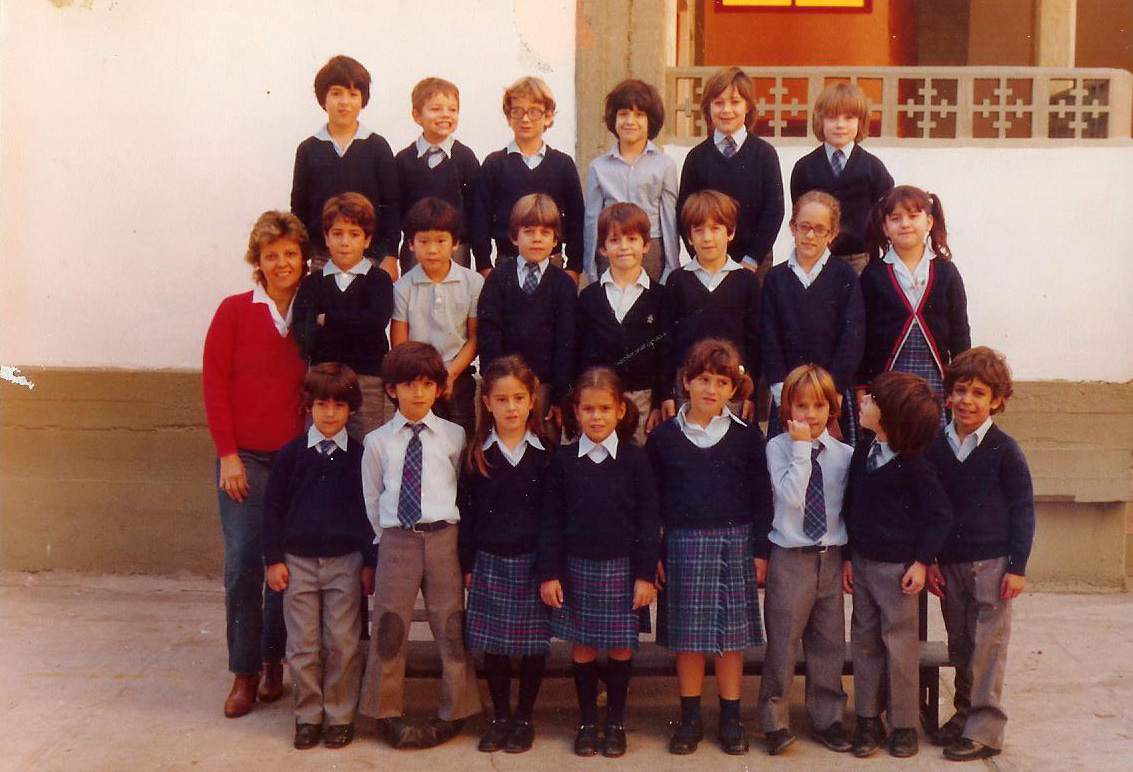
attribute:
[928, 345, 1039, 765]
kid — group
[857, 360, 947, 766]
kid — group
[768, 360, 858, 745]
kid — group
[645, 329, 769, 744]
kid — group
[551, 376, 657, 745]
kid — group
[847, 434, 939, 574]
sweater — blue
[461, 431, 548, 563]
sweater — blue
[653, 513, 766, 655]
skirt — plaid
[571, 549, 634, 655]
skirt — plaid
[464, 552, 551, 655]
skirt — plaid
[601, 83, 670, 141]
hair — brown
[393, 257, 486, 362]
shirt — short sleeved